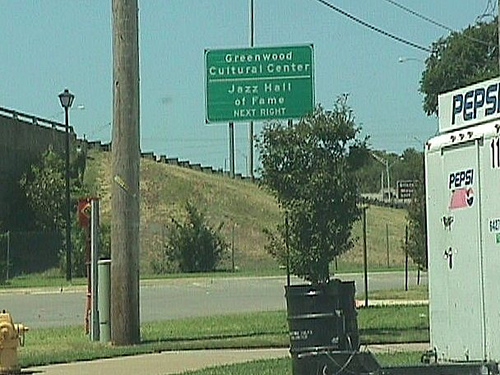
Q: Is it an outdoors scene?
A: Yes, it is outdoors.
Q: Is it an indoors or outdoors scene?
A: It is outdoors.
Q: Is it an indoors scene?
A: No, it is outdoors.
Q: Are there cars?
A: No, there are no cars.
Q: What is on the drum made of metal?
A: The tree is on the drum.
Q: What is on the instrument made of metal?
A: The tree is on the drum.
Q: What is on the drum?
A: The tree is on the drum.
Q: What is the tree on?
A: The tree is on the drum.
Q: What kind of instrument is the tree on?
A: The tree is on the drum.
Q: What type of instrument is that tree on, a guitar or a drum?
A: The tree is on a drum.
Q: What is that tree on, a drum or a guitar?
A: The tree is on a drum.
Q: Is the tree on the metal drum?
A: Yes, the tree is on the drum.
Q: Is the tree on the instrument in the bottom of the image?
A: Yes, the tree is on the drum.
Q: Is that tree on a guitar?
A: No, the tree is on the drum.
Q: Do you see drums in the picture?
A: Yes, there is a drum.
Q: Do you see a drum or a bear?
A: Yes, there is a drum.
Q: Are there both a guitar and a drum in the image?
A: No, there is a drum but no guitars.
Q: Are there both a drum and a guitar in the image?
A: No, there is a drum but no guitars.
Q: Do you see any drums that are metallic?
A: Yes, there is a metal drum.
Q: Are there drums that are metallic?
A: Yes, there is a drum that is metallic.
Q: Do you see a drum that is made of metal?
A: Yes, there is a drum that is made of metal.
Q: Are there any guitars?
A: No, there are no guitars.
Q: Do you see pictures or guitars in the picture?
A: No, there are no guitars or pictures.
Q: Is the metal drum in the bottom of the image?
A: Yes, the drum is in the bottom of the image.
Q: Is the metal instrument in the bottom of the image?
A: Yes, the drum is in the bottom of the image.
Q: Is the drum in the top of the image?
A: No, the drum is in the bottom of the image.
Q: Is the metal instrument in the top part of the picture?
A: No, the drum is in the bottom of the image.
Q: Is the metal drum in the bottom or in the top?
A: The drum is in the bottom of the image.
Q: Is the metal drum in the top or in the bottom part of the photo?
A: The drum is in the bottom of the image.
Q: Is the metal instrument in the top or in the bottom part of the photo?
A: The drum is in the bottom of the image.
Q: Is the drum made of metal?
A: Yes, the drum is made of metal.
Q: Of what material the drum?
A: The drum is made of metal.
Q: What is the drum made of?
A: The drum is made of metal.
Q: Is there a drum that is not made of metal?
A: No, there is a drum but it is made of metal.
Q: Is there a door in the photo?
A: Yes, there is a door.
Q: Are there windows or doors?
A: Yes, there is a door.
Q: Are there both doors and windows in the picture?
A: No, there is a door but no windows.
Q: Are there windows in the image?
A: No, there are no windows.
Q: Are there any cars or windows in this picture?
A: No, there are no windows or cars.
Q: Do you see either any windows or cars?
A: No, there are no windows or cars.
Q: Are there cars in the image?
A: No, there are no cars.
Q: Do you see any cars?
A: No, there are no cars.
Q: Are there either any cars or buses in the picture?
A: No, there are no cars or buses.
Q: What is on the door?
A: The sign is on the door.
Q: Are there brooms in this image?
A: No, there are no brooms.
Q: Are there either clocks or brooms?
A: No, there are no brooms or clocks.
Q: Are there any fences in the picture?
A: Yes, there is a fence.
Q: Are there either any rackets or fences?
A: Yes, there is a fence.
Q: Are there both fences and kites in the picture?
A: No, there is a fence but no kites.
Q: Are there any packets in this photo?
A: No, there are no packets.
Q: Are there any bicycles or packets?
A: No, there are no packets or bicycles.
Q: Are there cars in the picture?
A: No, there are no cars.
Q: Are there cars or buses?
A: No, there are no cars or buses.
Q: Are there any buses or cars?
A: No, there are no cars or buses.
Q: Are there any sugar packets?
A: No, there are no sugar packets.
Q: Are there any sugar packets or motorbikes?
A: No, there are no sugar packets or motorbikes.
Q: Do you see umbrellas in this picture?
A: No, there are no umbrellas.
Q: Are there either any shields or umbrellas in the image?
A: No, there are no umbrellas or shields.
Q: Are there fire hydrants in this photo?
A: Yes, there is a fire hydrant.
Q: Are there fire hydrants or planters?
A: Yes, there is a fire hydrant.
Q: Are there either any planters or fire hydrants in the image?
A: Yes, there is a fire hydrant.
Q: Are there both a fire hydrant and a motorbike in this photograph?
A: No, there is a fire hydrant but no motorcycles.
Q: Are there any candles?
A: No, there are no candles.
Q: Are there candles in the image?
A: No, there are no candles.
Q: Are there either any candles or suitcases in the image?
A: No, there are no candles or suitcases.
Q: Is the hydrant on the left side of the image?
A: Yes, the hydrant is on the left of the image.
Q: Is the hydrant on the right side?
A: No, the hydrant is on the left of the image.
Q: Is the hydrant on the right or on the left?
A: The hydrant is on the left of the image.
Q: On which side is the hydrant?
A: The hydrant is on the left of the image.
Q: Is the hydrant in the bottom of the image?
A: Yes, the hydrant is in the bottom of the image.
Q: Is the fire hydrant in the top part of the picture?
A: No, the fire hydrant is in the bottom of the image.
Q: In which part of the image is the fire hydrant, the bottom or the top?
A: The fire hydrant is in the bottom of the image.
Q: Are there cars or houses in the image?
A: No, there are no cars or houses.